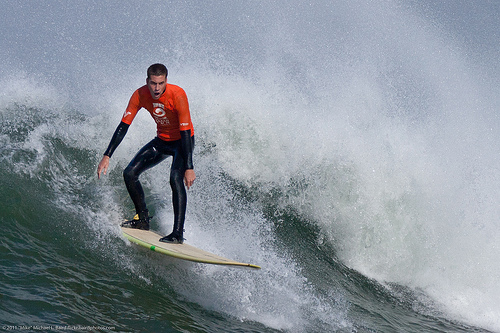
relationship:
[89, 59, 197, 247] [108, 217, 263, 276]
man on a surfboard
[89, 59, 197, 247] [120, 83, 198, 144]
man wearing a t-shirt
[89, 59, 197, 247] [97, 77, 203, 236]
body suit wearing a body suit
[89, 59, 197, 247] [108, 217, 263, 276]
body suit on a surfboard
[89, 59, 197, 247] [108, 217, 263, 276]
man riding on a surfboard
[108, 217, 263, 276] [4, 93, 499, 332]
surfboard in ocean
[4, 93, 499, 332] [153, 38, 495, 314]
ocean has mist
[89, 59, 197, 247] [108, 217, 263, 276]
man standing on a surfboard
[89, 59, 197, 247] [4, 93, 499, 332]
man surfing in ocean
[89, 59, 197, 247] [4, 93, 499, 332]
man in ocean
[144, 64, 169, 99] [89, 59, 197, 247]
head of a man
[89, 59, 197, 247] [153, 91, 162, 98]
man has a mouth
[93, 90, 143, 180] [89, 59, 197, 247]
right arm of a man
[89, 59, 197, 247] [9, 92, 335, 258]
man riding wave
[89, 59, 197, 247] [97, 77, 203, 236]
man has a body suit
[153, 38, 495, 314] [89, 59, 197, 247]
mist behind man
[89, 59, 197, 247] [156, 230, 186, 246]
man wearing surf shoe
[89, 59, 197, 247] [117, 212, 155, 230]
man wearing surf shoe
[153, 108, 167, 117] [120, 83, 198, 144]
logo on t-shirt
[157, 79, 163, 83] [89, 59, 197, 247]
eye brow of man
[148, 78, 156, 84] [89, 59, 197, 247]
eye brow of man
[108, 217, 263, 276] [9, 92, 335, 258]
surfboard on a wave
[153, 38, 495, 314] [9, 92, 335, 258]
mist from a wave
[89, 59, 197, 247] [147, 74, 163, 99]
man has a face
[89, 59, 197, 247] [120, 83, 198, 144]
man has a t-shirt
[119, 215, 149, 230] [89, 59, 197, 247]
right foot of man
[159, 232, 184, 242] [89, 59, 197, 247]
left foot of man